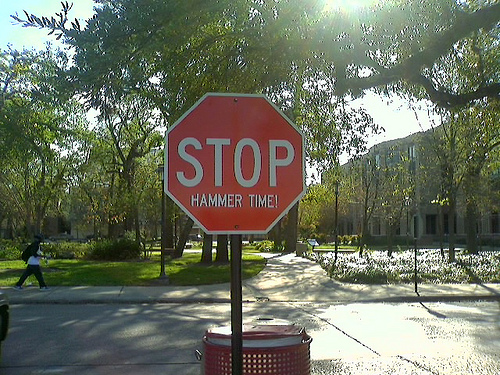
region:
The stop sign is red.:
[146, 83, 326, 280]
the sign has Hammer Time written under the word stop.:
[184, 177, 311, 217]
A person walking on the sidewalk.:
[18, 226, 58, 316]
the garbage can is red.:
[199, 306, 334, 373]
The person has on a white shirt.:
[27, 226, 49, 305]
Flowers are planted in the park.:
[335, 231, 497, 287]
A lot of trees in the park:
[16, 116, 158, 255]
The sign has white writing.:
[176, 134, 306, 195]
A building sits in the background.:
[342, 151, 492, 269]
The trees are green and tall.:
[12, 107, 177, 211]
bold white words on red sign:
[182, 140, 295, 196]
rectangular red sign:
[160, 85, 322, 235]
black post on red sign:
[199, 217, 264, 356]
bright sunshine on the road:
[308, 292, 432, 355]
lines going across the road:
[323, 310, 370, 361]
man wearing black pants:
[11, 262, 66, 297]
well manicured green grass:
[96, 260, 139, 285]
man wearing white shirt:
[19, 246, 69, 277]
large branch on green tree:
[14, 10, 121, 65]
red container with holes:
[169, 291, 326, 366]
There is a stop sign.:
[147, 80, 334, 374]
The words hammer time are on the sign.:
[185, 187, 293, 214]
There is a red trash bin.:
[193, 310, 316, 373]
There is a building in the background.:
[307, 122, 497, 253]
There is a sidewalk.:
[5, 281, 499, 307]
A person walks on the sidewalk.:
[15, 230, 54, 297]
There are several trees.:
[307, 70, 496, 285]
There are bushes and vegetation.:
[30, 228, 156, 258]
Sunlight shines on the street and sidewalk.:
[245, 242, 499, 373]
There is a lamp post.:
[321, 168, 354, 269]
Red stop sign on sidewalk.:
[151, 83, 326, 311]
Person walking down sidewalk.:
[12, 230, 58, 299]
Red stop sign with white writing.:
[160, 86, 317, 244]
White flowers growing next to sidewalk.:
[318, 246, 498, 281]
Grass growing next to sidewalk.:
[76, 258, 152, 286]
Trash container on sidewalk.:
[192, 319, 322, 374]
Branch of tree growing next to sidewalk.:
[92, 1, 499, 106]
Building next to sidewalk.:
[348, 116, 498, 243]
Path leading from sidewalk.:
[248, 244, 340, 294]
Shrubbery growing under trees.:
[60, 227, 150, 268]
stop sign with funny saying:
[160, 87, 313, 248]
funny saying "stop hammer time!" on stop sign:
[170, 123, 295, 218]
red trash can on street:
[192, 306, 320, 372]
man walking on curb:
[9, 223, 61, 294]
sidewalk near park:
[0, 238, 497, 314]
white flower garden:
[326, 241, 498, 295]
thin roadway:
[4, 274, 495, 371]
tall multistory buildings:
[324, 119, 496, 253]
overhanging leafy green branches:
[22, 0, 499, 165]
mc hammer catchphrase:
[174, 128, 301, 218]